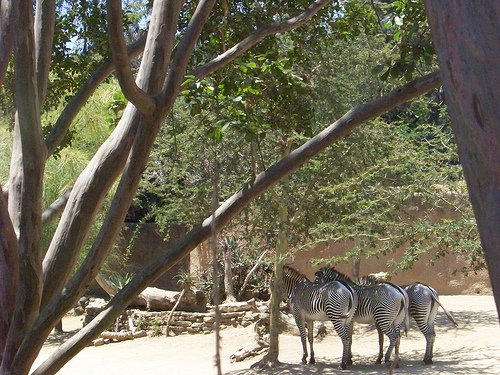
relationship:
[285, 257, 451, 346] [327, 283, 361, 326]
zebras have butts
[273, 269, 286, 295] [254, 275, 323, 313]
head nt visible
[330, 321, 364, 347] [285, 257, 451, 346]
leg of zebras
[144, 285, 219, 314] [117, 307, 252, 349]
log by wall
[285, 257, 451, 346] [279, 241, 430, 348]
zebras in group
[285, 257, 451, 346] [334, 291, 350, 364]
zebras have leg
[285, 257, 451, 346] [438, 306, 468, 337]
zebras have tails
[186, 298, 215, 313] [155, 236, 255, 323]
edge of wood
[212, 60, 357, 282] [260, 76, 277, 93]
trees have leaves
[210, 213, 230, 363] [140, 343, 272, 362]
stick in ground